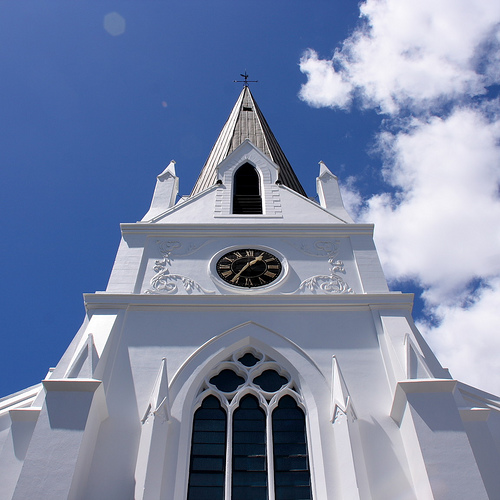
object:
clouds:
[428, 199, 494, 254]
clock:
[215, 243, 286, 290]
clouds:
[433, 313, 500, 344]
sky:
[0, 2, 497, 380]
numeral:
[244, 277, 253, 288]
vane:
[231, 68, 262, 85]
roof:
[192, 69, 305, 195]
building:
[0, 69, 499, 500]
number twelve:
[245, 250, 255, 257]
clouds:
[296, 2, 498, 115]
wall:
[119, 217, 372, 333]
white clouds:
[390, 146, 496, 263]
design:
[283, 237, 357, 295]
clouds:
[375, 98, 454, 161]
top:
[231, 67, 263, 108]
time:
[204, 240, 291, 291]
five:
[258, 276, 266, 284]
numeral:
[234, 252, 244, 258]